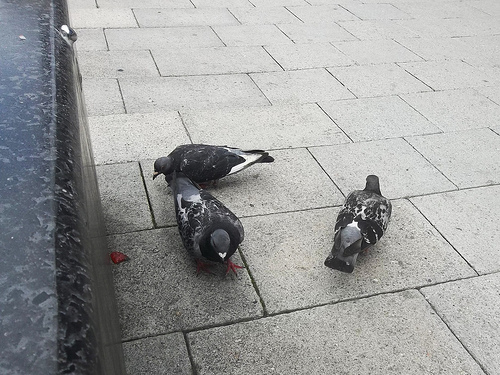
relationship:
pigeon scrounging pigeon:
[147, 138, 275, 183] [324, 171, 394, 273]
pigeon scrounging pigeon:
[167, 173, 246, 274] [324, 171, 394, 273]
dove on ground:
[147, 139, 274, 189] [2, 0, 497, 372]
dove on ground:
[161, 172, 250, 272] [2, 0, 497, 372]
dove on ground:
[319, 171, 395, 278] [2, 0, 497, 372]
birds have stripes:
[151, 143, 391, 276] [358, 205, 368, 224]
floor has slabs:
[62, 0, 496, 372] [88, 37, 468, 308]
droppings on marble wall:
[60, 23, 71, 34] [1, 0, 117, 373]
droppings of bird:
[60, 23, 71, 34] [322, 170, 395, 278]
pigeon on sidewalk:
[158, 126, 265, 190] [115, 49, 465, 349]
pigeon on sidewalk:
[341, 160, 407, 270] [115, 49, 465, 349]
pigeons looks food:
[323, 174, 398, 274] [234, 186, 337, 297]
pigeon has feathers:
[169, 173, 246, 280] [321, 157, 420, 293]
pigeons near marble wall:
[155, 150, 405, 289] [17, 82, 117, 292]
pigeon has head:
[169, 173, 246, 280] [210, 229, 231, 259]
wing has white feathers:
[330, 193, 391, 239] [343, 200, 371, 237]